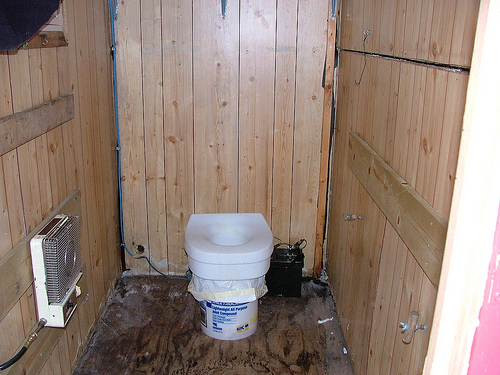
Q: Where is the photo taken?
A: Outhouse.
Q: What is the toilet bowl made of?
A: Bucket.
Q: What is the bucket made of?
A: Plastic.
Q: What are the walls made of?
A: Wood.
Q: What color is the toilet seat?
A: White.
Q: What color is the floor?
A: Brown.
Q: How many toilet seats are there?
A: One.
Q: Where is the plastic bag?
A: In the bucket.